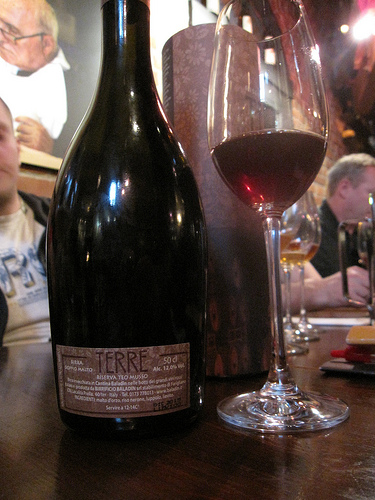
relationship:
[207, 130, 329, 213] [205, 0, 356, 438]
wine in a glass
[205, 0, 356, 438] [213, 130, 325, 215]
glass has wine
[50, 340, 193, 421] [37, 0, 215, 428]
label on bottle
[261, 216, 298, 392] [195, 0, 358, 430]
stem on glass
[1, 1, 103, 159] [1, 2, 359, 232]
picture on wall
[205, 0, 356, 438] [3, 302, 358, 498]
glass on table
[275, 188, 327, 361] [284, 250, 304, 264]
glasses of wine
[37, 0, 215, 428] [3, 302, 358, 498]
bottle on table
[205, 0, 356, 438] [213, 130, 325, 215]
glass of wine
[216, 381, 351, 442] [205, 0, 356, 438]
base of glass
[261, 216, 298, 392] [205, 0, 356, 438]
stem of glass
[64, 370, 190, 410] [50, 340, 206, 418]
words on label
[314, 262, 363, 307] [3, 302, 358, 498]
hand on table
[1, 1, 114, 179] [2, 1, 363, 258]
picture on wall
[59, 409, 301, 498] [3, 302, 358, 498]
shadow on table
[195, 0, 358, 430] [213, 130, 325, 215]
glass of wine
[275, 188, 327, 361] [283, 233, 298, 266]
glasses of wine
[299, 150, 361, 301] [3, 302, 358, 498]
man at table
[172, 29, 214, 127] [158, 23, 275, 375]
print on wrap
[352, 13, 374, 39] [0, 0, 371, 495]
lights in bar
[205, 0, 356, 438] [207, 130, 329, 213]
glass has wine